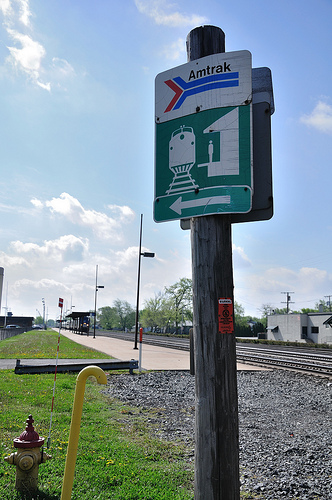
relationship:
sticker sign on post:
[214, 297, 235, 337] [186, 29, 231, 499]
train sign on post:
[150, 59, 277, 229] [186, 29, 231, 499]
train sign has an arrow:
[150, 59, 277, 229] [164, 196, 232, 212]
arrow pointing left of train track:
[164, 196, 232, 212] [72, 323, 332, 381]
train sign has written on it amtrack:
[150, 59, 277, 229] [189, 58, 235, 79]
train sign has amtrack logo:
[150, 59, 277, 229] [161, 73, 240, 110]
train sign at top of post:
[150, 59, 277, 229] [186, 29, 231, 499]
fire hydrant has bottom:
[7, 413, 51, 495] [4, 449, 57, 493]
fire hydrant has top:
[7, 413, 51, 495] [13, 416, 45, 448]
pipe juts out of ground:
[59, 362, 107, 500] [6, 369, 330, 500]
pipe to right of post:
[59, 362, 107, 500] [186, 29, 231, 499]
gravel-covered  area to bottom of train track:
[124, 374, 330, 496] [72, 323, 332, 381]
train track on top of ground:
[72, 323, 332, 381] [6, 369, 330, 500]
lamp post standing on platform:
[130, 207, 155, 351] [84, 336, 258, 371]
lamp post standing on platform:
[91, 266, 107, 341] [84, 336, 258, 371]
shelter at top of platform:
[69, 309, 96, 336] [84, 336, 258, 371]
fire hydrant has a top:
[7, 413, 51, 495] [13, 416, 45, 448]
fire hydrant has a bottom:
[7, 413, 51, 495] [4, 449, 57, 493]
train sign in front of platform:
[150, 59, 277, 229] [84, 336, 258, 371]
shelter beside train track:
[69, 309, 96, 336] [72, 323, 332, 381]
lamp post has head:
[130, 207, 155, 351] [137, 248, 155, 261]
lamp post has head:
[91, 266, 107, 341] [99, 283, 104, 291]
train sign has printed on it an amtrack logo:
[150, 59, 277, 229] [161, 73, 240, 110]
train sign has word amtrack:
[150, 59, 277, 229] [189, 58, 235, 79]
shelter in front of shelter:
[69, 309, 96, 336] [56, 318, 70, 329]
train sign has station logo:
[150, 59, 277, 229] [167, 123, 240, 184]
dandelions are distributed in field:
[95, 457, 119, 477] [6, 380, 144, 494]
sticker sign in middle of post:
[214, 297, 235, 337] [186, 29, 231, 499]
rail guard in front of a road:
[22, 364, 143, 372] [0, 359, 120, 367]